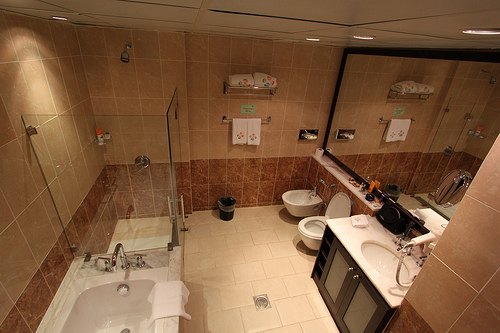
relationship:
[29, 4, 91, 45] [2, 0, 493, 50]
light on ceiling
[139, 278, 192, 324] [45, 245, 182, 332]
towel on tub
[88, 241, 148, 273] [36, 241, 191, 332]
faucet on tub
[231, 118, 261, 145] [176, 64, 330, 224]
towel on wall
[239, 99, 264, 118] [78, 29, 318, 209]
sign on wall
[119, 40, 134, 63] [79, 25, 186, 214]
showerhead on wall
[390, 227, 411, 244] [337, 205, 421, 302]
left knob on sink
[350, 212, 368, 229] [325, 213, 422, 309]
wash cloth on sink counter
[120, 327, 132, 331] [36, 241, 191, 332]
drain hole in tub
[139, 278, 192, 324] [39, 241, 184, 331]
towel on bathtub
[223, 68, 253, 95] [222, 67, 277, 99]
towel on rack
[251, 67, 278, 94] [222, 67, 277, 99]
towel on rack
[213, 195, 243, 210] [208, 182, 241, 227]
bag in can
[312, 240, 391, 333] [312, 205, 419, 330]
closed doors to vanity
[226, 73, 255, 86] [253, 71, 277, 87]
towel on towel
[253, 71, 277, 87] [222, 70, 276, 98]
towel on rack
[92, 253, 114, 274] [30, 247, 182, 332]
valve on bathtub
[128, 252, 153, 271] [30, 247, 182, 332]
valve on bathtub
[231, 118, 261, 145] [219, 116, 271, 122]
towel on rack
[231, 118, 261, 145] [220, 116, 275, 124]
towel on rack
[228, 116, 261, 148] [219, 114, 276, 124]
towel on rack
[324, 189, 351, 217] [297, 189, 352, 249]
cover on toilet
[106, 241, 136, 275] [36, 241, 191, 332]
faucet on tub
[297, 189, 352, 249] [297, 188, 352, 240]
toilet has seat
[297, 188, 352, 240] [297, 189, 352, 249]
seat on toilet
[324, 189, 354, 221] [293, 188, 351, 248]
cover on toilet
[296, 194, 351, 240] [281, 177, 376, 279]
seat on toilet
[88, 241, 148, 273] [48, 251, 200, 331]
faucet on tub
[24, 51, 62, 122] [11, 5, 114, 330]
reflection on wall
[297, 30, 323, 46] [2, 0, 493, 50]
lights in ceiling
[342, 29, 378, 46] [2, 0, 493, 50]
lights in ceiling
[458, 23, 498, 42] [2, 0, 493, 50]
lights in ceiling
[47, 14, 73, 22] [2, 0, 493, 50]
light in ceiling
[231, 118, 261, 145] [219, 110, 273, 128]
towel on rack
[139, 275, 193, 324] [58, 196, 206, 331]
towel on edge of tub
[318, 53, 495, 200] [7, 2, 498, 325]
reflection in bathroom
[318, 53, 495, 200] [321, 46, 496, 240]
reflection in mirror